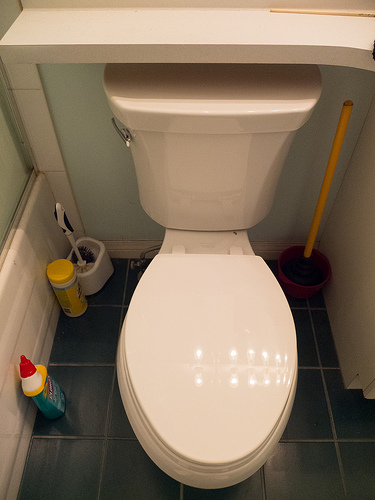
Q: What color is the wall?
A: Blue.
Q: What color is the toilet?
A: White.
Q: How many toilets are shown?
A: One.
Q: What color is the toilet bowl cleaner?
A: Black and white.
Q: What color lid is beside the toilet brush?
A: Yellow.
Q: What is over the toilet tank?
A: Shelf.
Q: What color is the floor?
A: Navy blue.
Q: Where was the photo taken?
A: In a bathroom.